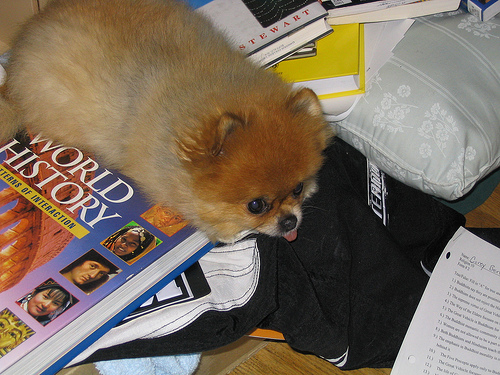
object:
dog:
[0, 0, 336, 242]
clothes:
[61, 137, 469, 369]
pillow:
[326, 0, 500, 202]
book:
[0, 123, 224, 373]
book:
[272, 24, 364, 101]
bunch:
[294, 13, 415, 122]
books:
[189, 0, 331, 71]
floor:
[55, 334, 272, 375]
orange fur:
[230, 135, 290, 188]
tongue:
[280, 229, 299, 243]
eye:
[241, 192, 272, 214]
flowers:
[392, 85, 413, 101]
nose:
[275, 214, 298, 233]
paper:
[391, 226, 500, 375]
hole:
[445, 250, 453, 258]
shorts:
[322, 137, 500, 371]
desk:
[223, 185, 500, 374]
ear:
[288, 86, 325, 121]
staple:
[449, 230, 466, 246]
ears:
[210, 110, 236, 159]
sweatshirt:
[59, 209, 357, 367]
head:
[105, 229, 148, 262]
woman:
[96, 225, 156, 260]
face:
[199, 122, 327, 244]